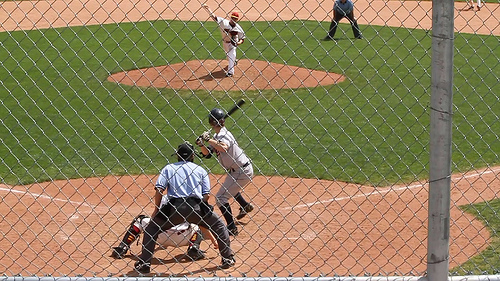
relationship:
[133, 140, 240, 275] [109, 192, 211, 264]
umpire standing behind catcher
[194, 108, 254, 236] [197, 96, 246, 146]
baseball player holding baseballbat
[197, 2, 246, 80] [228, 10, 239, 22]
pitcher wearing a cap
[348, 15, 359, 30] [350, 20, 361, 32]
hand on knee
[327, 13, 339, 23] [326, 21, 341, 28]
hand on knee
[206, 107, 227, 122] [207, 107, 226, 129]
helmet on head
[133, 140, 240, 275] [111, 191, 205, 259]
umpire behind catcher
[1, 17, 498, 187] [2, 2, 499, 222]
grass in infield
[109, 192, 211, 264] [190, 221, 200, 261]
catcher has leg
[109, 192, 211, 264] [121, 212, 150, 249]
catcher has leg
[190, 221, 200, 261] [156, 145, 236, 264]
leg in front of umpire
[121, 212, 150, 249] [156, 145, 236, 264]
leg in front of umpire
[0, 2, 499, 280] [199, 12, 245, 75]
fence behind player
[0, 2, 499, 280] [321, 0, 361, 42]
fence behind player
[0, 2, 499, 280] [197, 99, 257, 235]
fence behind player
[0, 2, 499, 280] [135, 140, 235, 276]
fence behind player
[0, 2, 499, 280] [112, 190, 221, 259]
fence behind player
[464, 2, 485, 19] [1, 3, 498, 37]
fielder in dirt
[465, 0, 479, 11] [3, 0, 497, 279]
man on field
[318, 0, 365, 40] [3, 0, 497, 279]
man on field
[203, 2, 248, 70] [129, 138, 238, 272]
man on man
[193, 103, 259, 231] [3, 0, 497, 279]
man on field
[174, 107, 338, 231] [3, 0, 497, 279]
player in field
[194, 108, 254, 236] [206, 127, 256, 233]
baseball player wearing uniform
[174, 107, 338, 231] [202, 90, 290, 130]
player holding bat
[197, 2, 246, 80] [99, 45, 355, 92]
pitcher on mound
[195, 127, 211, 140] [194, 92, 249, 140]
hand holding bat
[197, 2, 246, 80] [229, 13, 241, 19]
pitcher wearing hat